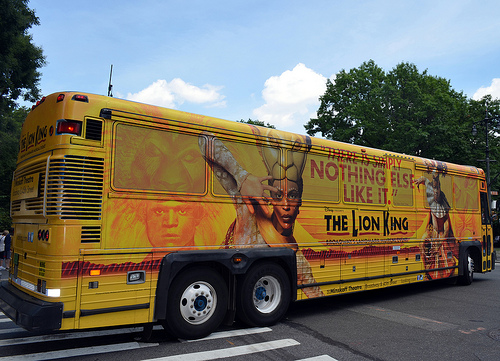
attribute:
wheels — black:
[168, 259, 291, 319]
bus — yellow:
[15, 93, 497, 278]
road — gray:
[347, 322, 484, 346]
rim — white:
[177, 283, 215, 320]